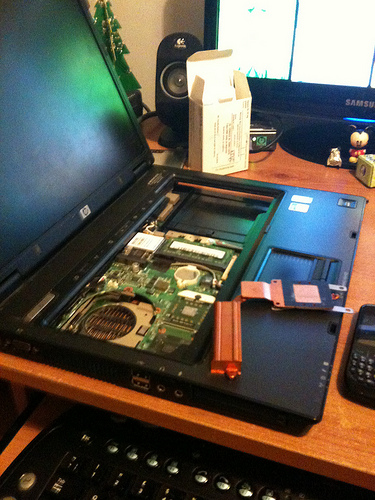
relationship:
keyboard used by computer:
[4, 412, 253, 499] [201, 0, 373, 169]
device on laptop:
[212, 273, 349, 381] [1, 58, 367, 431]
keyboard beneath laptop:
[0, 412, 304, 498] [1, 2, 366, 432]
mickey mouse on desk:
[349, 125, 369, 163] [277, 162, 311, 185]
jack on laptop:
[172, 387, 182, 396] [1, 2, 366, 432]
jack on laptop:
[154, 381, 164, 392] [1, 2, 366, 432]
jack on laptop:
[130, 368, 151, 389] [1, 2, 366, 432]